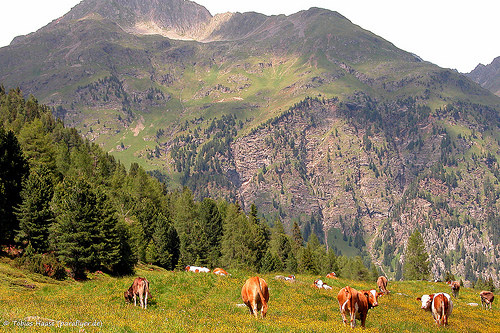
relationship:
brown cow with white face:
[417, 287, 455, 322] [419, 294, 431, 309]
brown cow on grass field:
[416, 292, 453, 329] [1, 250, 498, 331]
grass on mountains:
[110, 90, 262, 125] [0, 1, 498, 158]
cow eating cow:
[124, 276, 153, 309] [239, 274, 269, 321]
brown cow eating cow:
[416, 292, 453, 329] [239, 274, 269, 321]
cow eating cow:
[375, 274, 390, 294] [239, 274, 269, 321]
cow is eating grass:
[124, 276, 153, 309] [25, 261, 494, 331]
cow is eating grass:
[240, 276, 269, 320] [25, 261, 494, 331]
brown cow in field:
[416, 292, 453, 329] [0, 252, 498, 332]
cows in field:
[449, 279, 463, 298] [0, 252, 498, 332]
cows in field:
[480, 290, 495, 311] [0, 252, 498, 332]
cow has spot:
[337, 285, 384, 330] [369, 285, 377, 296]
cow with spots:
[179, 263, 211, 273] [192, 268, 200, 273]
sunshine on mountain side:
[125, 11, 235, 50] [1, 0, 498, 296]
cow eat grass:
[124, 275, 159, 310] [1, 269, 498, 331]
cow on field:
[240, 276, 269, 320] [8, 260, 498, 331]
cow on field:
[124, 276, 153, 309] [8, 260, 498, 331]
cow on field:
[337, 285, 384, 330] [8, 260, 498, 331]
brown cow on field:
[416, 292, 453, 329] [8, 260, 498, 331]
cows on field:
[475, 287, 495, 313] [8, 260, 498, 331]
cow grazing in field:
[337, 285, 384, 330] [149, 247, 479, 331]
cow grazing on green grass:
[235, 261, 379, 324] [30, 0, 472, 266]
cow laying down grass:
[240, 276, 269, 320] [200, 271, 473, 326]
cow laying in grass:
[310, 274, 335, 292] [218, 269, 456, 331]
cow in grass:
[238, 274, 268, 319] [2, 251, 495, 330]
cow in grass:
[124, 276, 153, 309] [2, 251, 495, 330]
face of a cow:
[368, 290, 380, 306] [337, 285, 384, 330]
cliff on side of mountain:
[238, 104, 495, 276] [161, 9, 498, 259]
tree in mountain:
[34, 112, 164, 244] [0, 0, 498, 287]